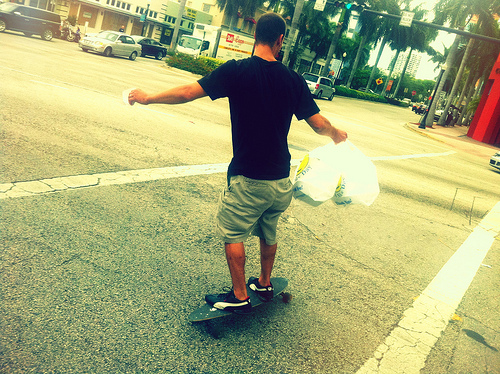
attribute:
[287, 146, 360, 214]
decal — yellow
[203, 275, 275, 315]
shoes — black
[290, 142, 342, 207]
bag — white, yellow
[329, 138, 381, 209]
bag — white, yellow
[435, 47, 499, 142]
structure — RED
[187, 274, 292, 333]
skate board — green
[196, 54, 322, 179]
shirt — black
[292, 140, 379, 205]
bags — plastic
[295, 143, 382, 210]
bags — GROCERY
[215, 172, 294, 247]
shorts — khaki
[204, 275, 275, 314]
sneakers — black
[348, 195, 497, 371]
lines — broken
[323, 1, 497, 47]
traffic post — green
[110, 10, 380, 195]
arms — extended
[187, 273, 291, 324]
skateboard — black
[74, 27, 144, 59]
car — white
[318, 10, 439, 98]
trees — tall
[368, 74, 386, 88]
sign — red and yellow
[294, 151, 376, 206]
trash bag — white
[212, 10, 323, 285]
he — skateboard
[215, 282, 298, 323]
feet — MAN'S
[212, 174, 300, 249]
pants — green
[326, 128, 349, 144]
hand — PERSONS